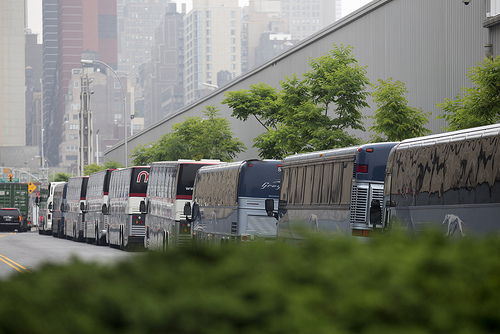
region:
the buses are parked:
[26, 138, 423, 292]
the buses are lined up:
[25, 143, 489, 282]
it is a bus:
[195, 158, 278, 237]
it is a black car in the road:
[1, 205, 23, 231]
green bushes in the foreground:
[30, 246, 497, 329]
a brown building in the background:
[1, 1, 53, 152]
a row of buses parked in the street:
[43, 158, 223, 251]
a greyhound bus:
[436, 210, 471, 240]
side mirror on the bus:
[264, 192, 279, 221]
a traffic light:
[6, 166, 17, 185]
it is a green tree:
[227, 46, 382, 151]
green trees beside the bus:
[263, 45, 411, 139]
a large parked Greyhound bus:
[386, 119, 498, 244]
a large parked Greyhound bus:
[263, 139, 391, 243]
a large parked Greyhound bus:
[191, 157, 281, 248]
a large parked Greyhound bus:
[142, 155, 219, 254]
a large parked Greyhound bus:
[107, 163, 152, 248]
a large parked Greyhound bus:
[81, 168, 113, 243]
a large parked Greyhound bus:
[63, 175, 84, 240]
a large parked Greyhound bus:
[51, 180, 65, 235]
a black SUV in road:
[0, 207, 21, 233]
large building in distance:
[177, 1, 239, 108]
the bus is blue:
[185, 152, 300, 273]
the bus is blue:
[258, 128, 406, 265]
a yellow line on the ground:
[0, 254, 25, 268]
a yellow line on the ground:
[2, 250, 31, 273]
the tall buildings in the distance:
[0, 0, 343, 180]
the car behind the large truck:
[1, 207, 23, 232]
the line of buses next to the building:
[35, 120, 496, 252]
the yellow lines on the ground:
[0, 229, 32, 271]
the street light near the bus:
[78, 57, 128, 167]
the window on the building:
[204, 10, 210, 18]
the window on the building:
[65, 144, 70, 151]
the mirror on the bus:
[264, 197, 274, 214]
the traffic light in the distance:
[7, 172, 12, 182]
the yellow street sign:
[26, 179, 36, 195]